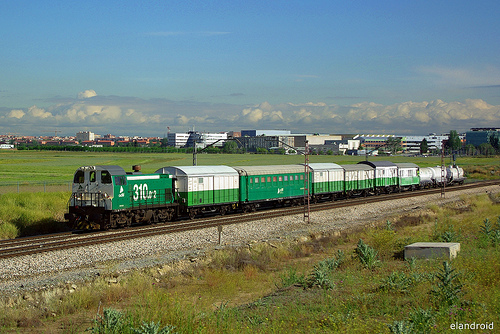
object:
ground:
[0, 147, 499, 333]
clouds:
[0, 86, 499, 141]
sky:
[0, 0, 499, 135]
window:
[113, 175, 128, 186]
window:
[74, 169, 84, 185]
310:
[131, 182, 153, 203]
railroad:
[0, 178, 498, 263]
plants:
[353, 240, 381, 269]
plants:
[302, 264, 334, 287]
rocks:
[152, 275, 161, 284]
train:
[63, 160, 464, 231]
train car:
[301, 163, 345, 195]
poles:
[302, 140, 309, 224]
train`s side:
[108, 168, 436, 231]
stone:
[403, 240, 464, 262]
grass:
[473, 215, 493, 237]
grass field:
[0, 191, 499, 331]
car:
[230, 164, 313, 206]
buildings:
[164, 132, 229, 147]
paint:
[246, 171, 311, 201]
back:
[69, 169, 114, 215]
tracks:
[0, 177, 499, 257]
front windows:
[99, 169, 113, 184]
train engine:
[63, 162, 174, 234]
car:
[153, 164, 242, 207]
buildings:
[237, 130, 289, 137]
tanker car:
[447, 163, 465, 182]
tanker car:
[417, 168, 432, 182]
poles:
[437, 141, 446, 198]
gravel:
[18, 280, 26, 289]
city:
[0, 116, 499, 160]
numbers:
[130, 182, 140, 202]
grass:
[426, 261, 467, 308]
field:
[0, 151, 499, 334]